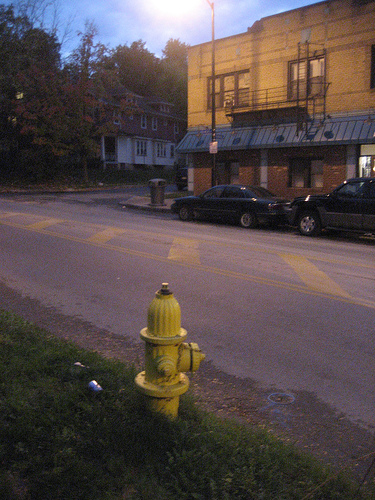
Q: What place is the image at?
A: It is at the road.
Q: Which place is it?
A: It is a road.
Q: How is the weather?
A: It is clear.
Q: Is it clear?
A: Yes, it is clear.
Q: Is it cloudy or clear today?
A: It is clear.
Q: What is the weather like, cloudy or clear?
A: It is clear.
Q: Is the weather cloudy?
A: No, it is clear.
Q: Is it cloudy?
A: No, it is clear.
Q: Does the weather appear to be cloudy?
A: No, it is clear.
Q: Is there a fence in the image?
A: No, there are no fences.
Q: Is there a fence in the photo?
A: No, there are no fences.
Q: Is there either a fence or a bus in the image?
A: No, there are no fences or buses.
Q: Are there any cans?
A: Yes, there is a can.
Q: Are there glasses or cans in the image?
A: Yes, there is a can.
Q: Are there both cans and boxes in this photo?
A: No, there is a can but no boxes.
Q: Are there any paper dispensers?
A: No, there are no paper dispensers.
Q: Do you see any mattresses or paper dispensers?
A: No, there are no paper dispensers or mattresses.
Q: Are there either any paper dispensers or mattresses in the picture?
A: No, there are no paper dispensers or mattresses.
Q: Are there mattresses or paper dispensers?
A: No, there are no paper dispensers or mattresses.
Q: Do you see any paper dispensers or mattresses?
A: No, there are no paper dispensers or mattresses.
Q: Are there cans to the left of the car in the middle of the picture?
A: Yes, there is a can to the left of the car.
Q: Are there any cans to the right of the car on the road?
A: No, the can is to the left of the car.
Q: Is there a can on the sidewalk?
A: Yes, there is a can on the sidewalk.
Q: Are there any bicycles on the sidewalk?
A: No, there is a can on the sidewalk.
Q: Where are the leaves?
A: The leaves are on the ground.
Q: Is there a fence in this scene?
A: No, there are no fences.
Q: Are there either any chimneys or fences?
A: No, there are no fences or chimneys.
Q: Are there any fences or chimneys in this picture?
A: No, there are no fences or chimneys.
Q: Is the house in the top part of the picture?
A: Yes, the house is in the top of the image.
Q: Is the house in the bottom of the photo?
A: No, the house is in the top of the image.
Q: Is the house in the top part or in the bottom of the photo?
A: The house is in the top of the image.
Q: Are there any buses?
A: No, there are no buses.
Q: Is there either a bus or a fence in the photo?
A: No, there are no buses or fences.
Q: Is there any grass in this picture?
A: Yes, there is grass.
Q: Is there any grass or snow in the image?
A: Yes, there is grass.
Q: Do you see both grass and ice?
A: No, there is grass but no ice.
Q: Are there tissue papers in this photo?
A: No, there are no tissue papers.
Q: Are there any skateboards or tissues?
A: No, there are no tissues or skateboards.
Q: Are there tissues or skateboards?
A: No, there are no tissues or skateboards.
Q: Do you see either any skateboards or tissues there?
A: No, there are no tissues or skateboards.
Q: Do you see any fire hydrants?
A: Yes, there is a fire hydrant.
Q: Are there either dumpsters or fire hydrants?
A: Yes, there is a fire hydrant.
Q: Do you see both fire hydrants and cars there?
A: Yes, there are both a fire hydrant and a car.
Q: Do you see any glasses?
A: No, there are no glasses.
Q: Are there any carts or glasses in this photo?
A: No, there are no glasses or carts.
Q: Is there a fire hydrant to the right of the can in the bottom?
A: Yes, there is a fire hydrant to the right of the can.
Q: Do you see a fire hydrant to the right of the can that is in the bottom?
A: Yes, there is a fire hydrant to the right of the can.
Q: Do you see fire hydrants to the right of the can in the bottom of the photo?
A: Yes, there is a fire hydrant to the right of the can.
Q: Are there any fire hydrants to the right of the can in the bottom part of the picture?
A: Yes, there is a fire hydrant to the right of the can.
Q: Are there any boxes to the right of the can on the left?
A: No, there is a fire hydrant to the right of the can.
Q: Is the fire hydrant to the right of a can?
A: Yes, the fire hydrant is to the right of a can.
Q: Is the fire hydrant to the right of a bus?
A: No, the fire hydrant is to the right of a can.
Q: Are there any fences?
A: No, there are no fences.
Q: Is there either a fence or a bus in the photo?
A: No, there are no fences or buses.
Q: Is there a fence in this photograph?
A: No, there are no fences.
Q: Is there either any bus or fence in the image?
A: No, there are no fences or buses.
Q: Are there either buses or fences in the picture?
A: No, there are no fences or buses.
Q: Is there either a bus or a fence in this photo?
A: No, there are no buses or fences.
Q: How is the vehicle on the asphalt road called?
A: The vehicle is a car.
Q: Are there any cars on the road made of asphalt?
A: Yes, there is a car on the road.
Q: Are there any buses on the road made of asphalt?
A: No, there is a car on the road.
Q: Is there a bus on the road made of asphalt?
A: No, there is a car on the road.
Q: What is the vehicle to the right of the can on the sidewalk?
A: The vehicle is a car.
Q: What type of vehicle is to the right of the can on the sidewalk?
A: The vehicle is a car.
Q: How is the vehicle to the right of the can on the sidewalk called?
A: The vehicle is a car.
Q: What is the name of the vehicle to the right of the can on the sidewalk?
A: The vehicle is a car.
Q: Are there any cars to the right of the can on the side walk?
A: Yes, there is a car to the right of the can.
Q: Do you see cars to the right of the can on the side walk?
A: Yes, there is a car to the right of the can.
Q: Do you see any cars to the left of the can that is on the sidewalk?
A: No, the car is to the right of the can.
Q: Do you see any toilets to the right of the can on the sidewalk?
A: No, there is a car to the right of the can.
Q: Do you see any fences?
A: No, there are no fences.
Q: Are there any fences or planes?
A: No, there are no fences or planes.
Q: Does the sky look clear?
A: Yes, the sky is clear.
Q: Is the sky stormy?
A: No, the sky is clear.